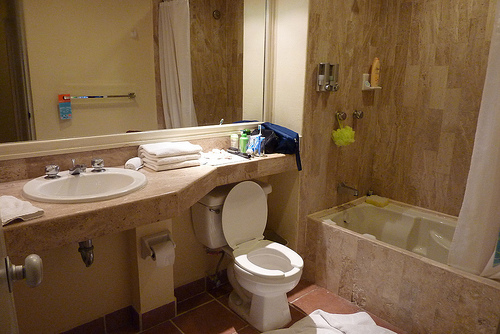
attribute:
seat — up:
[212, 180, 271, 248]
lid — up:
[220, 169, 272, 247]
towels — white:
[138, 140, 202, 172]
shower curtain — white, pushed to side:
[157, 3, 204, 130]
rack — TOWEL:
[58, 90, 140, 104]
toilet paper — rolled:
[144, 237, 174, 267]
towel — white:
[230, 305, 402, 331]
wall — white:
[390, 17, 468, 123]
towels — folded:
[124, 133, 211, 168]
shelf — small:
[347, 75, 379, 95]